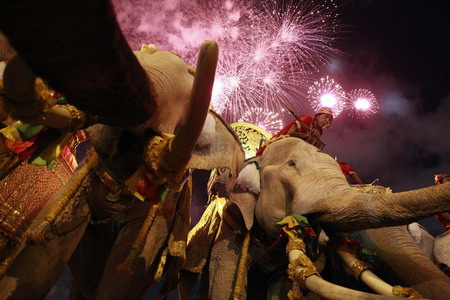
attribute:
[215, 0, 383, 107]
fireworks — bright, purple, pink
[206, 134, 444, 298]
elephant — gray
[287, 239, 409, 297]
tusks — decorated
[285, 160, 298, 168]
eye — black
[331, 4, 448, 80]
sky — black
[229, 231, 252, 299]
rope — gold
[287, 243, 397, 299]
tusk — decorated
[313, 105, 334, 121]
hat — gold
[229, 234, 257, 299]
braids — gold